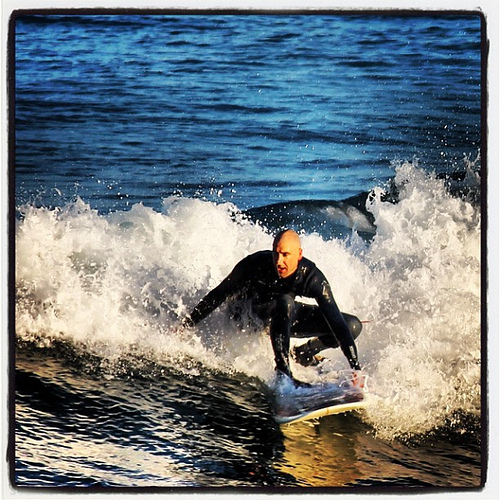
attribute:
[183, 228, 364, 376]
man — surfing, bald, bending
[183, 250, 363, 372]
wet suit — black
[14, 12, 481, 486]
water — blue, wavy, deep, dark, glistening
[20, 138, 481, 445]
wave — white